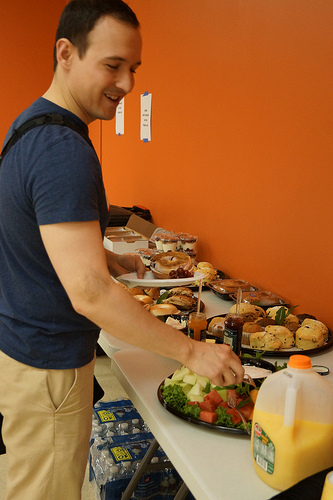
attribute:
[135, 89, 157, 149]
sign — taped, paper, white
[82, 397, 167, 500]
water — bottled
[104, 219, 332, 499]
table — banquet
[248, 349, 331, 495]
gallon — empty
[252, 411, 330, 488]
juice — orange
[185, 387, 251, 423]
fruit — fresh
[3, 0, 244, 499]
man — selecting, smiling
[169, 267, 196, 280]
grapes — red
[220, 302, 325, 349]
pastries — assorted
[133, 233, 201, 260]
parfaits — stacked, yogurt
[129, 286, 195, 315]
bagels — assorted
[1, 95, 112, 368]
shirt — blue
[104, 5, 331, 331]
wall — orange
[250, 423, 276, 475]
sticker — green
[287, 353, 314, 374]
top — orange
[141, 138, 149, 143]
tape — blue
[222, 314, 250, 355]
jar — opened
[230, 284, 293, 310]
container — covered, take-out, plastic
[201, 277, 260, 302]
container — covered, take-out, plastic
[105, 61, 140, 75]
eyes — closed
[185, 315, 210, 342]
jellie — opened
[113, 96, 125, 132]
paper — taped